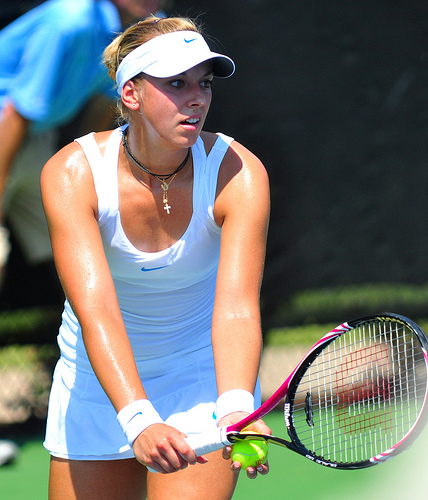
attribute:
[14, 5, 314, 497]
woman — blonde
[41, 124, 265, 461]
dress — white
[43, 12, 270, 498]
woman — wears, wearing, holding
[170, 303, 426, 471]
racket — black, red , tennis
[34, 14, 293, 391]
woman — holding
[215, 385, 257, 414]
sweatband — white 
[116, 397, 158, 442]
sweatband — white 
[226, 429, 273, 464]
ball — tennis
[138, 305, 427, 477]
racket — pink, black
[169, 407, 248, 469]
handle — white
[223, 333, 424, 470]
racket — tennis, white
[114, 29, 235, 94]
hat — white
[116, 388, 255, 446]
sweatbands — white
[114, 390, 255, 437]
wrists — womans 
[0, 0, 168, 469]
person — behind 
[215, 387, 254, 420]
sweatband — white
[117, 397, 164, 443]
sweatband — white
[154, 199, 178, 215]
cross — hangs 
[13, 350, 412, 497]
court —  green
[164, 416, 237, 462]
tape — grip 